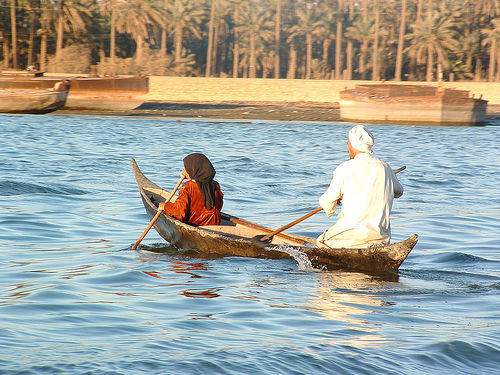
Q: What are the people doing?
A: Rowing a boat.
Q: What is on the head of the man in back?
A: A turban.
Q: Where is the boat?
A: On the water.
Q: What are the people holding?
A: Oars.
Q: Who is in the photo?
A: A man and a woman.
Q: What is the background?
A: The coast lined with palm trees.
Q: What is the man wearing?
A: All white.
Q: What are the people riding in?
A: A canoe.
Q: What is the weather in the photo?
A: Sunny.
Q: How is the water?
A: Blue with calm waves.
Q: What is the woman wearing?
A: A black head scarf.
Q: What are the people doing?
A: Rowing a in a canoe.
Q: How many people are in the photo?
A: Two.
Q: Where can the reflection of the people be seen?
A: In water.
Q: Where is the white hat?
A: On man's head.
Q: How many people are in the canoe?
A: 2.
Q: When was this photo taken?
A: During the day.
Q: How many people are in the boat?
A: Two.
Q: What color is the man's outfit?
A: White.